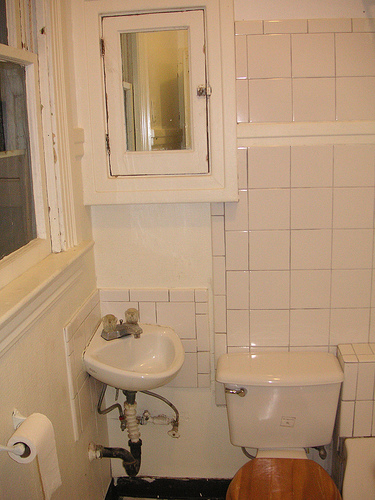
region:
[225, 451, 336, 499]
Brown toilet lid on toilet.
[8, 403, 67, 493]
Roll of white toilet paper.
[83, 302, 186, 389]
White corner sink on walls.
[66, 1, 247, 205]
White medicine cabinet on the wall.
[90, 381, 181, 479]
Sink plumbing under sink.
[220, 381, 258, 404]
Silver flushing handle on toilet.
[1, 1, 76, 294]
Window on side of wall.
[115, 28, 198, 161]
Mirror on cabinet door.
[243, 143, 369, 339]
White tile on the wall.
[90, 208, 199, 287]
White colored plastered walls.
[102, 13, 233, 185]
old mirror with white frame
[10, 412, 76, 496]
half roll of white toilet paper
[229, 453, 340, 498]
shinny wood toilet seat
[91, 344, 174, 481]
plumbing underneath white sink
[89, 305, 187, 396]
small corner white hand sink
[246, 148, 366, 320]
white square tile on bathroom wall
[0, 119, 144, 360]
old window next to hand sink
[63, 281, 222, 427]
sink surrounded by white tile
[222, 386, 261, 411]
chrome flush handle on toilet seat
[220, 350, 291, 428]
light shinning on toilet top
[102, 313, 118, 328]
plastic knob on faucet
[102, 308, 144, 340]
chrome faucet on white sink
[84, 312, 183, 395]
small sink attached to wall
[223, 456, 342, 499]
woodent seat on white toilet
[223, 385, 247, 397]
metal flush handle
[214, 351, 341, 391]
white top on toilet tank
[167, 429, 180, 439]
valve under sink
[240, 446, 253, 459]
silver pipe behind toilet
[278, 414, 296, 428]
small sticker on tank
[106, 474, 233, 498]
black floor under sink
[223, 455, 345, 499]
wooden toilet seat cover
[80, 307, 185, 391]
small corner sink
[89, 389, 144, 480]
rusty piping for the sink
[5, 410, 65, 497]
a half roll of toilet paper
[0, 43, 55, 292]
a window on the side of the wall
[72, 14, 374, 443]
white square tiles on the wall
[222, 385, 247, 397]
metal toilet flushing handle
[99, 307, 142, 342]
metal faucet head for the sink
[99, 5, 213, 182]
medicine cabinet with built in mirror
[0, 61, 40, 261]
bathroom reflection in the window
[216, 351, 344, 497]
Most of a white toilet with wooden seat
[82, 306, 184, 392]
White porcilin corner sink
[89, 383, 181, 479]
Exposed bathroom sink plumbing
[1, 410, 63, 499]
A white toilet paper holder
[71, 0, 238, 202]
A white mirrored bathroom cabinet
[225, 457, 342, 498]
Part of the top of a wooden toilet seat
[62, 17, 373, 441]
White bathroom wall tile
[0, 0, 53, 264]
Part of a bathroom window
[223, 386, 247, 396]
A silver toilet flush handle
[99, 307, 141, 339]
A two knob bathroom faucet